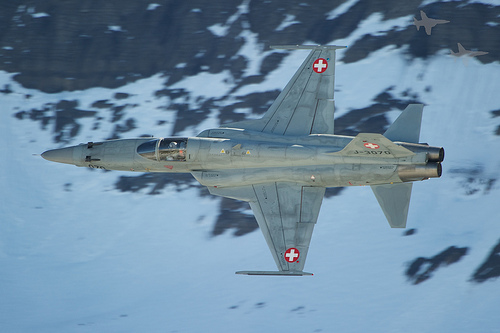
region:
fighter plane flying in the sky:
[30, 32, 467, 296]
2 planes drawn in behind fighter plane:
[402, 5, 497, 75]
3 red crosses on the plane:
[260, 40, 390, 283]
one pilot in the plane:
[147, 122, 194, 177]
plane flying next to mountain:
[3, 22, 497, 329]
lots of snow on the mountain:
[7, 20, 499, 326]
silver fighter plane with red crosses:
[9, 29, 488, 296]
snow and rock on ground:
[0, 1, 498, 328]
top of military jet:
[42, 43, 444, 275]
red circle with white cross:
[312, 56, 328, 72]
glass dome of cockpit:
[137, 136, 188, 159]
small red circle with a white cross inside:
[312, 53, 329, 78]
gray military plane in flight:
[36, 36, 461, 282]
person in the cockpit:
[136, 131, 196, 172]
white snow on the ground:
[13, 163, 499, 325]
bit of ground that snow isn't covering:
[405, 236, 468, 285]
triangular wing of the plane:
[232, 191, 337, 285]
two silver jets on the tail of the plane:
[410, 138, 454, 186]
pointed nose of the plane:
[36, 143, 77, 168]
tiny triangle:
[216, 143, 228, 157]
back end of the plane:
[341, 98, 454, 238]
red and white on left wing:
[278, 241, 299, 263]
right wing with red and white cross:
[308, 51, 328, 73]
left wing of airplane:
[205, 185, 325, 271]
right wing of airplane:
[256, 43, 332, 133]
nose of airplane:
[30, 136, 91, 167]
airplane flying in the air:
[90, 66, 440, 272]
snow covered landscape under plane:
[3, 111, 468, 311]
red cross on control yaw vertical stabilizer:
[361, 142, 383, 150]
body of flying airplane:
[38, 135, 483, 175]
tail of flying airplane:
[370, 103, 445, 229]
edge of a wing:
[320, 65, 349, 98]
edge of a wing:
[259, 265, 304, 297]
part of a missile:
[253, 267, 278, 281]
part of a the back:
[423, 141, 446, 187]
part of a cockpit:
[159, 142, 187, 167]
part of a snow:
[172, 277, 215, 322]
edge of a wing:
[248, 215, 281, 283]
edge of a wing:
[253, 223, 276, 261]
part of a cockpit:
[158, 130, 188, 154]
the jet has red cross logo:
[279, 238, 301, 272]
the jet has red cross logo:
[272, 228, 324, 296]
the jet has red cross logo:
[280, 245, 342, 306]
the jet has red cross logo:
[266, 211, 310, 276]